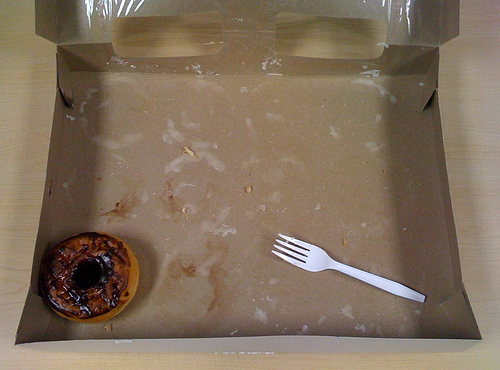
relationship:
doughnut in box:
[39, 232, 139, 324] [14, 1, 482, 355]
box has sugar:
[14, 1, 482, 355] [61, 55, 428, 335]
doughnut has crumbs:
[39, 232, 139, 324] [109, 109, 348, 246]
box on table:
[14, 1, 482, 355] [0, 0, 499, 369]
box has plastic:
[14, 1, 482, 355] [35, 0, 460, 47]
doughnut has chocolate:
[39, 232, 139, 324] [42, 232, 131, 320]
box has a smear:
[14, 1, 482, 355] [95, 170, 239, 327]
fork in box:
[271, 233, 427, 305] [14, 1, 482, 355]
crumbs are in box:
[109, 109, 348, 246] [14, 1, 482, 355]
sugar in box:
[61, 55, 428, 335] [14, 1, 482, 355]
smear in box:
[95, 170, 239, 327] [14, 1, 482, 355]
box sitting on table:
[14, 1, 482, 355] [0, 0, 499, 369]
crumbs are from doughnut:
[109, 109, 348, 246] [39, 232, 139, 324]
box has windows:
[14, 1, 482, 355] [108, 9, 388, 59]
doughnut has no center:
[39, 232, 139, 324] [72, 256, 103, 288]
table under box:
[0, 0, 499, 369] [14, 1, 482, 355]